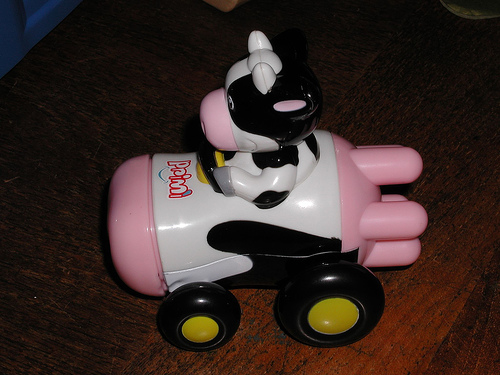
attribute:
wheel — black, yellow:
[155, 279, 245, 359]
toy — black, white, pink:
[96, 30, 428, 356]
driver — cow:
[191, 25, 326, 215]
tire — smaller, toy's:
[161, 279, 241, 352]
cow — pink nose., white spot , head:
[94, 28, 439, 348]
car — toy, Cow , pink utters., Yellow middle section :
[95, 23, 440, 343]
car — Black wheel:
[278, 253, 378, 343]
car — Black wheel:
[277, 261, 390, 345]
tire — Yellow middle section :
[312, 300, 355, 341]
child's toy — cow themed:
[107, 30, 427, 348]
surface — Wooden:
[4, 0, 497, 371]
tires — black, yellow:
[157, 261, 385, 354]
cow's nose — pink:
[198, 89, 235, 155]